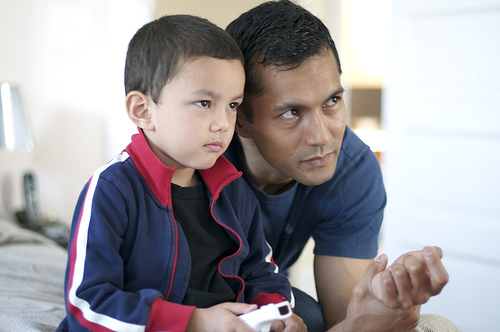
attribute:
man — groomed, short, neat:
[218, 3, 457, 315]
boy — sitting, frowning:
[93, 14, 235, 332]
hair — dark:
[254, 13, 298, 57]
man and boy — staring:
[99, 0, 365, 187]